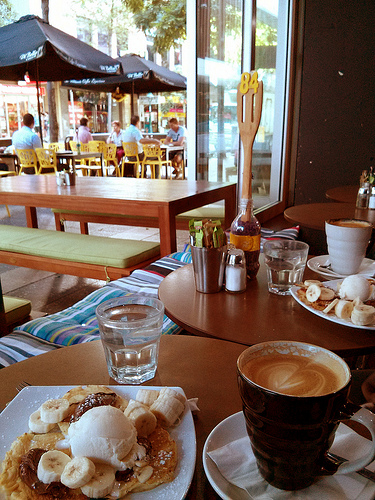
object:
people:
[74, 116, 93, 142]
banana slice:
[127, 407, 156, 438]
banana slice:
[40, 395, 68, 422]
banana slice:
[151, 391, 184, 427]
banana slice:
[135, 389, 158, 406]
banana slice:
[159, 387, 187, 404]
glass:
[96, 293, 163, 388]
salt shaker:
[226, 248, 245, 294]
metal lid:
[226, 248, 246, 267]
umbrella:
[61, 52, 186, 90]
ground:
[319, 95, 346, 117]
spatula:
[236, 70, 264, 223]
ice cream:
[66, 404, 137, 468]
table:
[0, 336, 371, 498]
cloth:
[38, 93, 198, 171]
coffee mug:
[235, 338, 375, 492]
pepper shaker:
[354, 180, 372, 211]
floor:
[124, 81, 179, 108]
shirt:
[12, 125, 41, 149]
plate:
[1, 384, 198, 499]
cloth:
[13, 268, 184, 348]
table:
[157, 249, 375, 351]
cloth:
[204, 434, 368, 498]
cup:
[323, 218, 373, 275]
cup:
[263, 239, 310, 296]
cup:
[96, 297, 166, 384]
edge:
[183, 409, 198, 500]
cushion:
[0, 224, 162, 270]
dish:
[202, 409, 375, 499]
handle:
[321, 404, 375, 475]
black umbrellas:
[0, 14, 124, 83]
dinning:
[0, 109, 186, 177]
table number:
[238, 72, 259, 95]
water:
[98, 303, 158, 376]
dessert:
[2, 383, 190, 498]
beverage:
[243, 352, 339, 394]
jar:
[229, 198, 261, 277]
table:
[139, 140, 186, 180]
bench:
[0, 221, 162, 284]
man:
[12, 113, 43, 176]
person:
[161, 117, 184, 180]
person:
[122, 115, 162, 178]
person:
[107, 119, 125, 174]